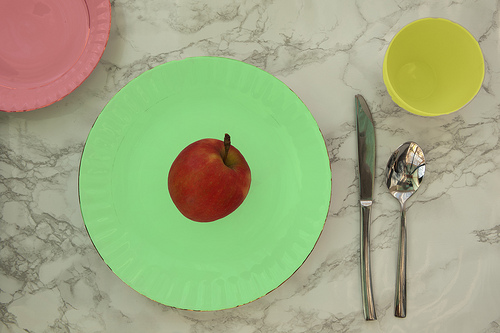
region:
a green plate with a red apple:
[78, 58, 333, 313]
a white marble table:
[2, 5, 499, 327]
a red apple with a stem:
[165, 130, 250, 221]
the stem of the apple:
[222, 131, 233, 158]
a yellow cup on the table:
[380, 24, 483, 116]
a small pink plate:
[1, 1, 113, 115]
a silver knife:
[355, 89, 378, 322]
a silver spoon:
[385, 140, 420, 317]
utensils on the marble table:
[353, 94, 424, 321]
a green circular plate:
[79, 55, 330, 312]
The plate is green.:
[71, 43, 338, 318]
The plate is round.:
[68, 43, 339, 317]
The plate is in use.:
[61, 34, 342, 328]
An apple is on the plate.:
[78, 40, 345, 316]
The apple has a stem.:
[149, 118, 278, 245]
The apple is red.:
[150, 111, 262, 229]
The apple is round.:
[163, 117, 269, 228]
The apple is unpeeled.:
[159, 111, 272, 238]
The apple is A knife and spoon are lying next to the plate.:
[61, 40, 430, 323]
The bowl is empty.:
[363, 3, 498, 120]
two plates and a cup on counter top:
[1, 12, 491, 321]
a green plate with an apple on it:
[73, 45, 330, 322]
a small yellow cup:
[387, 6, 483, 126]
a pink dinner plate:
[3, 0, 129, 129]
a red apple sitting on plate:
[168, 139, 258, 227]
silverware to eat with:
[348, 88, 433, 322]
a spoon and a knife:
[347, 91, 434, 328]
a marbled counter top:
[1, 132, 97, 323]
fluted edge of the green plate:
[96, 255, 259, 315]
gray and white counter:
[23, 160, 83, 331]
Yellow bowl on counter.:
[366, 14, 447, 90]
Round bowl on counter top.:
[396, 18, 499, 156]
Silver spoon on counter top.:
[379, 146, 422, 309]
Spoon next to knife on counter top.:
[363, 153, 448, 325]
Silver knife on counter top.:
[345, 93, 375, 267]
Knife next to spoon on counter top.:
[346, 80, 418, 271]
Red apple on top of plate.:
[166, 120, 257, 252]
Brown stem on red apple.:
[213, 138, 240, 164]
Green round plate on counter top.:
[75, 85, 293, 307]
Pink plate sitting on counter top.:
[0, 18, 85, 101]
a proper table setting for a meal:
[2, 1, 489, 318]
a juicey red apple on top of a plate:
[163, 133, 253, 229]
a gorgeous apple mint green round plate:
[71, 53, 331, 313]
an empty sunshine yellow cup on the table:
[381, 8, 488, 123]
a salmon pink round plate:
[0, 0, 109, 111]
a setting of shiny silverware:
[352, 93, 438, 325]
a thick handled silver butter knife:
[351, 93, 386, 330]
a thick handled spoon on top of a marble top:
[383, 143, 429, 325]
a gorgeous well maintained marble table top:
[244, 2, 377, 65]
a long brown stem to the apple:
[220, 129, 234, 162]